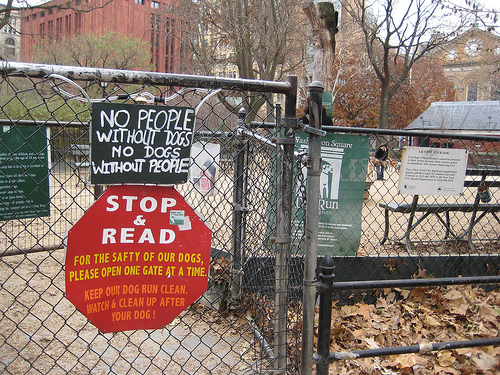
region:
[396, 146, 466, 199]
A white sign on a chain link fence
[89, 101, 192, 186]
A sign about people and dogs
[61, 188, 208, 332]
A red stop sign with a warning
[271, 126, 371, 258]
A green sign on a fence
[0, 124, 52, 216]
A green sign with a list of information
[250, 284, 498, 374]
A pile of leaves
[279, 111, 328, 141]
A lock for the fence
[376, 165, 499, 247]
A park bench behind the fence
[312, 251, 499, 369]
A black iron fence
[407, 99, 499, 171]
A small rest area with a roof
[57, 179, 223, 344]
THE SIGN IS RED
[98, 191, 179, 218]
THE SIGN SAYS STOP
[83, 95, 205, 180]
THE SIGN IS BLACK AND WHITE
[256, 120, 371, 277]
THE SIGN IS SQUARE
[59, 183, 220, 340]
THE SIGN IS OCTAGON SHAPED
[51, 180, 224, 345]
THIS IS A SIGN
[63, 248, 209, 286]
THE SIGN HAS YELLOW WRITING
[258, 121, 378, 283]
THE SIGN IS GREEN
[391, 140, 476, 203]
THE SIGN IS WHITE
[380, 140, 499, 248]
THE BENCH IS NEXT TO THE GREEN SIGN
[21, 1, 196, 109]
several storied brick building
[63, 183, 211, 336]
sign shaped like a traffic stop sign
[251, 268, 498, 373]
pile of fallen leaves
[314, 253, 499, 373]
metal fencing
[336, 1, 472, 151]
tree that has lost its leaves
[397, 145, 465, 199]
sign posted on chain link fencing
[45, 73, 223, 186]
sign hanging by a cord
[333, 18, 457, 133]
trees with autumn leaves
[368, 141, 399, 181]
person standing in enclosure with dogs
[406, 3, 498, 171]
building with a cross on its roof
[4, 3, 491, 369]
fenced in dog run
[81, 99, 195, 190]
black sign stating only people with dogs can enter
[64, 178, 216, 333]
red stop sign with rules for the dog run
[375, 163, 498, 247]
park bench inside the dog run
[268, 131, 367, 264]
green "Washington Square Dog Run" sign on fence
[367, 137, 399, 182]
person with dog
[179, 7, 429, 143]
trees are bare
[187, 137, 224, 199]
large trash can inside dog run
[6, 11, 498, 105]
older homes and buildings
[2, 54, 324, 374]
gate to get in dog run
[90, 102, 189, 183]
handwritten warning sign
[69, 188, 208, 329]
A stop sign with instructions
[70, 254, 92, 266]
The words are yellow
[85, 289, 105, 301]
The words are orange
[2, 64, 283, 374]
A chain link fence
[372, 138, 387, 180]
A person bending to a dog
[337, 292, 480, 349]
A pile of dead leaves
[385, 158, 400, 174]
a yellow dog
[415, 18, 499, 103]
A brown brick building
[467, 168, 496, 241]
The back of a bench